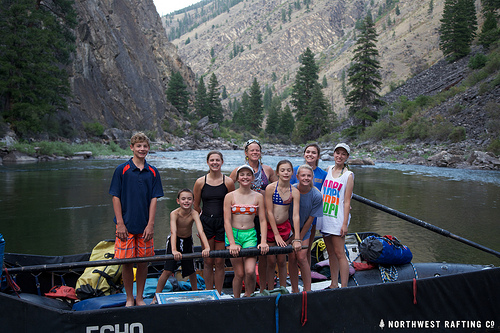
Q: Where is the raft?
A: On a river.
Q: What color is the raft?
A: Black.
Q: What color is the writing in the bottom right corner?
A: White.